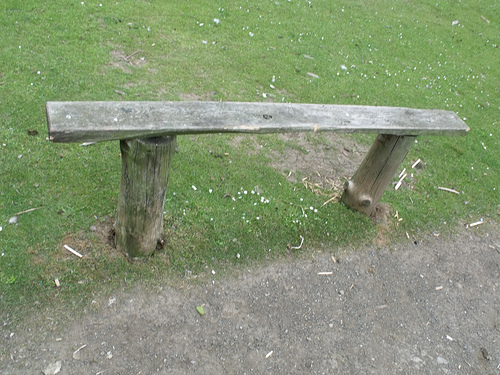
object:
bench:
[46, 100, 470, 258]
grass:
[208, 12, 341, 86]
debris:
[187, 22, 367, 87]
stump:
[113, 135, 179, 260]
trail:
[316, 249, 479, 348]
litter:
[287, 235, 305, 250]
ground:
[0, 180, 500, 375]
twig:
[287, 205, 305, 250]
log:
[46, 100, 470, 258]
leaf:
[387, 164, 458, 233]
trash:
[62, 244, 82, 257]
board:
[44, 99, 471, 143]